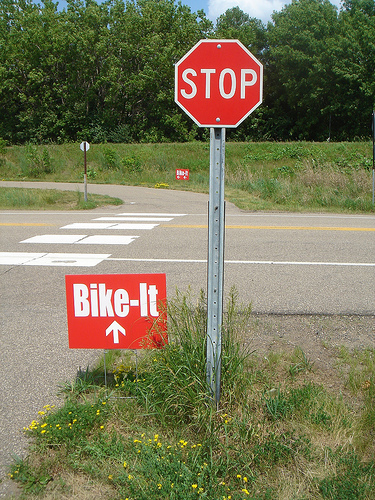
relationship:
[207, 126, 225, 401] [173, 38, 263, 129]
pole holding sign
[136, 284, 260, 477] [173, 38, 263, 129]
bush by sign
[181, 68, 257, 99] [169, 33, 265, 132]
lettering on sign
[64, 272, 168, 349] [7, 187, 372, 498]
red sign on side of road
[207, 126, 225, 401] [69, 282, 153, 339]
pole holding sign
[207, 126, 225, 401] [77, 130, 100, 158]
pole holding sign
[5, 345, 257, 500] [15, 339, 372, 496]
dandelion among grass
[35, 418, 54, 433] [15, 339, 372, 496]
dandelion among grass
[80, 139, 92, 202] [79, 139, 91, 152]
pole in sign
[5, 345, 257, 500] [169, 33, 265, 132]
dandelion around sign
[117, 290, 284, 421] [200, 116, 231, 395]
grass around pole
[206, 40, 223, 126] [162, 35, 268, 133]
bolts holding sign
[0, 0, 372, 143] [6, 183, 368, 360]
trees on other side of road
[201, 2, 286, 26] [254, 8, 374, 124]
clouds behind trees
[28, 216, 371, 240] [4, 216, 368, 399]
line painted on road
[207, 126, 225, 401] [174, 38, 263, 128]
pole for sign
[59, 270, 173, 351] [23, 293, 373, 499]
red sign on grass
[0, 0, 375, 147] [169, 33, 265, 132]
trees behind sign